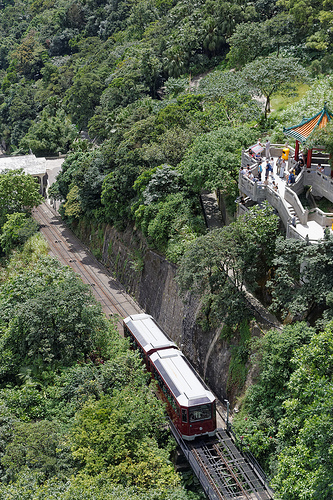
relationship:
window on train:
[180, 408, 189, 423] [121, 316, 218, 444]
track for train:
[34, 201, 148, 317] [121, 316, 218, 444]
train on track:
[121, 316, 218, 444] [34, 201, 148, 317]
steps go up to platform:
[281, 195, 307, 226] [237, 141, 303, 203]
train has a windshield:
[121, 316, 218, 444] [190, 404, 213, 422]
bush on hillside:
[163, 226, 196, 263] [0, 2, 332, 324]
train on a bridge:
[121, 316, 218, 444] [175, 430, 271, 500]